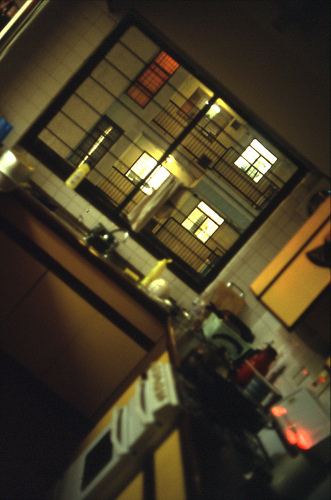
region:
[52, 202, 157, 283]
a kitchen sink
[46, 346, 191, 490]
a white oven unit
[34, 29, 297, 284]
a window in the kitchen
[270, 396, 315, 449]
red lights on the stove panel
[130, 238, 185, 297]
a bottle of dish liquid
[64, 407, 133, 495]
the oven window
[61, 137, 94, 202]
a bottle of soap on a ledge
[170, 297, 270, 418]
there is a teapot on the stove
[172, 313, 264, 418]
teapot on the stove top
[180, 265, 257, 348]
a wooden cutting board with a metal handle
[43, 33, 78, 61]
this is the wall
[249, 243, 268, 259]
the wall is made of tiles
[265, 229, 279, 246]
the tiles are white in color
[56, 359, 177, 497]
this is a gas cooker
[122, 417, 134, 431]
the cooker is white in color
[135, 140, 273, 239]
these are some windows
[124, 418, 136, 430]
the cooker is metallic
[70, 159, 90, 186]
this is a bottle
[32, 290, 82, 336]
this is a drawer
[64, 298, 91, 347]
the drawer is wooden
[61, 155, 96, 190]
dish soap in window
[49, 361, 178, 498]
small apartment size stove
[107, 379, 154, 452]
double handles on stove front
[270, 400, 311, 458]
red lights on stove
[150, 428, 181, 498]
yellow cabinet drawers beside stove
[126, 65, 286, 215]
balcony on building seen thru window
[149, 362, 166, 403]
knobs on stove front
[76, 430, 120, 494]
black glass on oven door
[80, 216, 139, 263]
chrome sink fixtures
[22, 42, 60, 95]
white tiles on kitchen wall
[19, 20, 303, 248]
a window in a kitchen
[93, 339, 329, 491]
a stove in the kitchen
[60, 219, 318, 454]
a kitchen area in a home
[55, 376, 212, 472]
the stove is white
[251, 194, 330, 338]
a yellow cabinet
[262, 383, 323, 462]
red light on a stove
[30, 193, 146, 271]
a faucet on the sink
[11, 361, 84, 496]
the floor is dark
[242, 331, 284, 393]
a red container on the counter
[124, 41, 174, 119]
a window with an orange curtain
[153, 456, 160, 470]
part of an edge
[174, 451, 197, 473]
part of an edge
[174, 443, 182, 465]
part of an edge